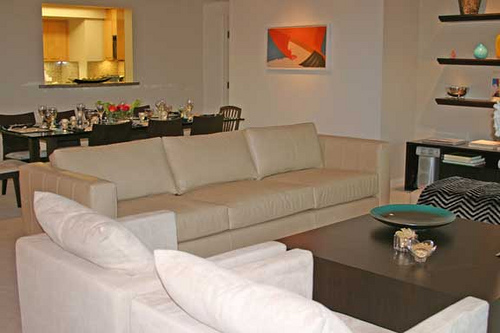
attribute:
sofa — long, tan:
[34, 123, 409, 258]